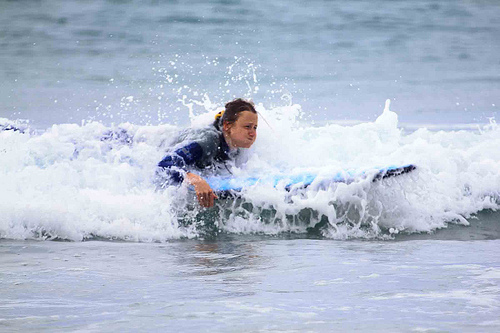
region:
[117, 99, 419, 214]
a woman on a blue surf board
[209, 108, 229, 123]
a yellow hair tie in a woman's head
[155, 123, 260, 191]
a blue wet suit on a woman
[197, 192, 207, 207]
a ring on a woman's finger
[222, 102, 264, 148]
a woman's face with it's mouth closed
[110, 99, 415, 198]
a woman paddling on a surf board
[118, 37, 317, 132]
water splashing in the air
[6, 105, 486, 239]
white water waves coming in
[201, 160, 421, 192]
a two toned blue surf board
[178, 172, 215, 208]
a woman's hand on a surf borad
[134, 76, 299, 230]
this is a woman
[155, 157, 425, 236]
this is a surfboard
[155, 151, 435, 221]
the surfboard is aqua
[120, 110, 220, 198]
woman wearing a wet suit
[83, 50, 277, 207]
the woman is wet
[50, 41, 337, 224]
the woman is in water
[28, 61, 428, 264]
woman is riding the surfboard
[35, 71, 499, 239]
this is a wave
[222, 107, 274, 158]
woman has cheeks puffed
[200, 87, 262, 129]
woman has brown hairt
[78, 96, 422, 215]
a woman swimming on a surf board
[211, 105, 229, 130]
a yellow hair tie on a woman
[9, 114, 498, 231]
white water crashing in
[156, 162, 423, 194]
a blue surfboard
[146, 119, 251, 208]
a blue wet suit on a woman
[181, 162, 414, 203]
a surfboard with a woman on it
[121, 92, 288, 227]
a woman lying on a board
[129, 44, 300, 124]
water splashing in the air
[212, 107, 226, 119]
yellow cord holding girl's hair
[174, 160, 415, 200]
blue and black surf board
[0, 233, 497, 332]
calm water in front of waves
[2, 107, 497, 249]
foam of waves on water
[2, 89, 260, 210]
woman making funny face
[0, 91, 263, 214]
woman clinging to surf board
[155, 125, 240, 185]
black wet suit on woman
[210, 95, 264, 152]
woman's head wearing pony tail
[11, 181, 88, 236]
patch of foamy waves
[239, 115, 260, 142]
face of woman wincing